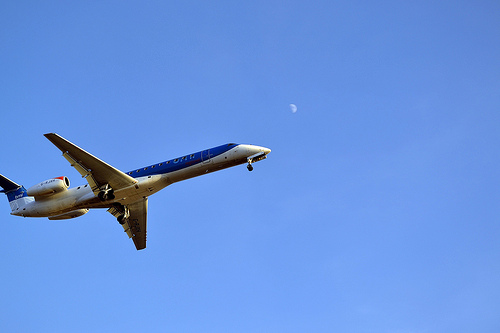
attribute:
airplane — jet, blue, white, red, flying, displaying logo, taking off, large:
[0, 132, 272, 251]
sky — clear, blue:
[0, 1, 499, 333]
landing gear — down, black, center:
[97, 183, 132, 226]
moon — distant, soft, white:
[289, 102, 299, 116]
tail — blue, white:
[0, 174, 33, 221]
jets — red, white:
[25, 175, 90, 222]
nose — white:
[237, 140, 272, 158]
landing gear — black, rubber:
[244, 158, 254, 172]